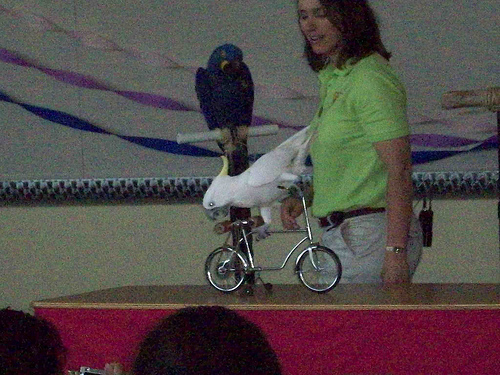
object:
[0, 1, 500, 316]
wall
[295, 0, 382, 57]
person's head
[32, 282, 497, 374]
stand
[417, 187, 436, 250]
walkie talkie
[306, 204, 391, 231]
belt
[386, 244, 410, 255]
watch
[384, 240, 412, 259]
wrist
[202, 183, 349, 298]
toy bicycle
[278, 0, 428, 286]
woman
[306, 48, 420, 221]
polo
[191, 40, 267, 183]
parrot